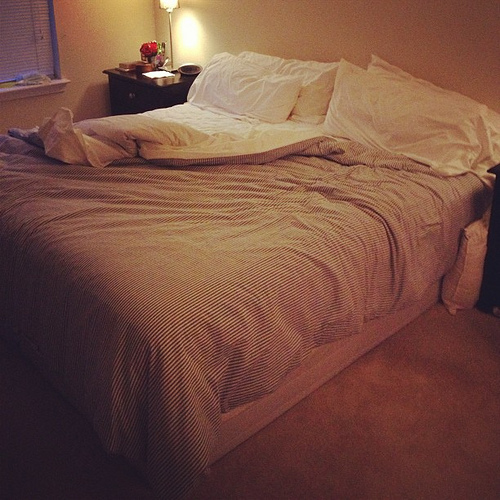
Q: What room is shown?
A: It is a bedroom.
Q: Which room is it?
A: It is a bedroom.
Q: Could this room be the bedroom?
A: Yes, it is the bedroom.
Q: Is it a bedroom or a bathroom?
A: It is a bedroom.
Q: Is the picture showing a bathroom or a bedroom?
A: It is showing a bedroom.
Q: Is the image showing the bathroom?
A: No, the picture is showing the bedroom.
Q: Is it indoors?
A: Yes, it is indoors.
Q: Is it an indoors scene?
A: Yes, it is indoors.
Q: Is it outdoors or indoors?
A: It is indoors.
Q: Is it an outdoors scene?
A: No, it is indoors.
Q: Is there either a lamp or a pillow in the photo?
A: Yes, there is a pillow.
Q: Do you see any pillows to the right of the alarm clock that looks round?
A: Yes, there is a pillow to the right of the alarm clock.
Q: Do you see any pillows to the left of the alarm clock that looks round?
A: No, the pillow is to the right of the alarm clock.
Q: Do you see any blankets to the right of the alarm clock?
A: No, there is a pillow to the right of the alarm clock.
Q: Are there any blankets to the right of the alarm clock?
A: No, there is a pillow to the right of the alarm clock.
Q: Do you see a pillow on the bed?
A: Yes, there is a pillow on the bed.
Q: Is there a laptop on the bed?
A: No, there is a pillow on the bed.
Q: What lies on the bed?
A: The pillow lies on the bed.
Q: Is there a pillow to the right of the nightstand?
A: Yes, there is a pillow to the right of the nightstand.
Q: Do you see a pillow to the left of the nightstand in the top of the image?
A: No, the pillow is to the right of the nightstand.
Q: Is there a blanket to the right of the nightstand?
A: No, there is a pillow to the right of the nightstand.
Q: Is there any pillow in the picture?
A: Yes, there is a pillow.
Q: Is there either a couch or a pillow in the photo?
A: Yes, there is a pillow.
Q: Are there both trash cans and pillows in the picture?
A: No, there is a pillow but no trash cans.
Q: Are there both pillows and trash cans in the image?
A: No, there is a pillow but no trash cans.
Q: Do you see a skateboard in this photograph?
A: No, there are no skateboards.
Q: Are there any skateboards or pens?
A: No, there are no skateboards or pens.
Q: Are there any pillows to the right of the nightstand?
A: Yes, there is a pillow to the right of the nightstand.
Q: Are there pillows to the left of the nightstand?
A: No, the pillow is to the right of the nightstand.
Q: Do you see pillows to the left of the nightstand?
A: No, the pillow is to the right of the nightstand.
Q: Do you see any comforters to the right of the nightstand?
A: No, there is a pillow to the right of the nightstand.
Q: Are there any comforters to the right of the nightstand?
A: No, there is a pillow to the right of the nightstand.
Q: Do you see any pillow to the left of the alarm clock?
A: No, the pillow is to the right of the alarm clock.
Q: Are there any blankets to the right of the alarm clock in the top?
A: No, there is a pillow to the right of the alarm clock.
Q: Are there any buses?
A: No, there are no buses.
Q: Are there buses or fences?
A: No, there are no buses or fences.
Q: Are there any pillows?
A: Yes, there is a pillow.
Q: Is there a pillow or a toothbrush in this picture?
A: Yes, there is a pillow.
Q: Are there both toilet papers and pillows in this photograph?
A: No, there is a pillow but no toilet papers.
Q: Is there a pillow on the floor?
A: Yes, there is a pillow on the floor.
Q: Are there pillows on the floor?
A: Yes, there is a pillow on the floor.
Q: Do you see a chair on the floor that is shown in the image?
A: No, there is a pillow on the floor.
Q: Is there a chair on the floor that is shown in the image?
A: No, there is a pillow on the floor.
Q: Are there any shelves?
A: No, there are no shelves.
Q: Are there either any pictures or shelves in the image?
A: No, there are no shelves or pictures.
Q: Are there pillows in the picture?
A: Yes, there are pillows.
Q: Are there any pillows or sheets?
A: Yes, there are pillows.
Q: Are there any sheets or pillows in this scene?
A: Yes, there are pillows.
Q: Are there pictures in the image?
A: No, there are no pictures.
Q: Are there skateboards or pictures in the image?
A: No, there are no pictures or skateboards.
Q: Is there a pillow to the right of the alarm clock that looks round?
A: Yes, there are pillows to the right of the alarm clock.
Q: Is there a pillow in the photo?
A: Yes, there is a pillow.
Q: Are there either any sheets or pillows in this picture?
A: Yes, there is a pillow.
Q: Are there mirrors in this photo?
A: No, there are no mirrors.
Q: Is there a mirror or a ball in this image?
A: No, there are no mirrors or balls.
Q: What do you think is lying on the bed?
A: The pillow is lying on the bed.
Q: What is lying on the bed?
A: The pillow is lying on the bed.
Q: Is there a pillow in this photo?
A: Yes, there are pillows.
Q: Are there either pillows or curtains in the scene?
A: Yes, there are pillows.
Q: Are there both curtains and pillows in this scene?
A: No, there are pillows but no curtains.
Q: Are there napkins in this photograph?
A: No, there are no napkins.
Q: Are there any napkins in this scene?
A: No, there are no napkins.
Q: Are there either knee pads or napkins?
A: No, there are no napkins or knee pads.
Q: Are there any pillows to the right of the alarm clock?
A: Yes, there are pillows to the right of the alarm clock.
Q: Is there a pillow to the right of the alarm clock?
A: Yes, there are pillows to the right of the alarm clock.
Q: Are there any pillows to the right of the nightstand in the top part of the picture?
A: Yes, there are pillows to the right of the nightstand.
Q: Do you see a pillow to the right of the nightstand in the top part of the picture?
A: Yes, there are pillows to the right of the nightstand.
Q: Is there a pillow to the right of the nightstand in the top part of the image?
A: Yes, there are pillows to the right of the nightstand.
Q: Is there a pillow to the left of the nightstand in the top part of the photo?
A: No, the pillows are to the right of the nightstand.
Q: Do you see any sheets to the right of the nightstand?
A: No, there are pillows to the right of the nightstand.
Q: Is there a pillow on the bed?
A: Yes, there are pillows on the bed.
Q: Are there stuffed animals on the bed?
A: No, there are pillows on the bed.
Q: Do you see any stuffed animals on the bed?
A: No, there are pillows on the bed.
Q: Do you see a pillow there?
A: Yes, there is a pillow.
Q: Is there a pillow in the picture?
A: Yes, there is a pillow.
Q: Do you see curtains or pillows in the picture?
A: Yes, there is a pillow.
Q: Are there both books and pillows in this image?
A: No, there is a pillow but no books.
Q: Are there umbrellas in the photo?
A: No, there are no umbrellas.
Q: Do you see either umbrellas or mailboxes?
A: No, there are no umbrellas or mailboxes.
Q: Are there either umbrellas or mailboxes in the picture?
A: No, there are no umbrellas or mailboxes.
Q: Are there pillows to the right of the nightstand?
A: Yes, there is a pillow to the right of the nightstand.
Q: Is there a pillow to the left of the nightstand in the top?
A: No, the pillow is to the right of the nightstand.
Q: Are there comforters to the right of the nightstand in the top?
A: No, there is a pillow to the right of the nightstand.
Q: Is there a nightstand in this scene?
A: Yes, there is a nightstand.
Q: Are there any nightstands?
A: Yes, there is a nightstand.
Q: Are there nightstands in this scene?
A: Yes, there is a nightstand.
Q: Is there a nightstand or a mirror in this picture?
A: Yes, there is a nightstand.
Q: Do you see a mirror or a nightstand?
A: Yes, there is a nightstand.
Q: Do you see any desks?
A: No, there are no desks.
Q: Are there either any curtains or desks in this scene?
A: No, there are no desks or curtains.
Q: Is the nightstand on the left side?
A: Yes, the nightstand is on the left of the image.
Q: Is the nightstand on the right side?
A: No, the nightstand is on the left of the image.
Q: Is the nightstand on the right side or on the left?
A: The nightstand is on the left of the image.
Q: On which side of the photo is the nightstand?
A: The nightstand is on the left of the image.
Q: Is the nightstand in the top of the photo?
A: Yes, the nightstand is in the top of the image.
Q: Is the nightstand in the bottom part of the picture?
A: No, the nightstand is in the top of the image.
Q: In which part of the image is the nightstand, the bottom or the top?
A: The nightstand is in the top of the image.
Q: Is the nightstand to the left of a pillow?
A: Yes, the nightstand is to the left of a pillow.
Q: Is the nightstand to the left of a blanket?
A: No, the nightstand is to the left of a pillow.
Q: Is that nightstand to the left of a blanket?
A: No, the nightstand is to the left of a pillow.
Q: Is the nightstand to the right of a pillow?
A: No, the nightstand is to the left of a pillow.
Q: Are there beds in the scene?
A: Yes, there is a bed.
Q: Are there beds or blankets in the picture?
A: Yes, there is a bed.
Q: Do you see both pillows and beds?
A: Yes, there are both a bed and a pillow.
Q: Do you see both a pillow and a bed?
A: Yes, there are both a bed and a pillow.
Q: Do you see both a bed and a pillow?
A: Yes, there are both a bed and a pillow.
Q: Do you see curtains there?
A: No, there are no curtains.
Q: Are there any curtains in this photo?
A: No, there are no curtains.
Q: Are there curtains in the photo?
A: No, there are no curtains.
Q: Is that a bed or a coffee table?
A: That is a bed.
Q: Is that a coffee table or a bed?
A: That is a bed.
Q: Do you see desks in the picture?
A: No, there are no desks.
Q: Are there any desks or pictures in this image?
A: No, there are no desks or pictures.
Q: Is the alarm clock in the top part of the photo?
A: Yes, the alarm clock is in the top of the image.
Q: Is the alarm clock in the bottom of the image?
A: No, the alarm clock is in the top of the image.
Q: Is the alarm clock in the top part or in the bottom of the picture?
A: The alarm clock is in the top of the image.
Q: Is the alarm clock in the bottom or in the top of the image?
A: The alarm clock is in the top of the image.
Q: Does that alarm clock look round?
A: Yes, the alarm clock is round.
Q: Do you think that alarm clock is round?
A: Yes, the alarm clock is round.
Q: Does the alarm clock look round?
A: Yes, the alarm clock is round.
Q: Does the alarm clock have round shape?
A: Yes, the alarm clock is round.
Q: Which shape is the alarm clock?
A: The alarm clock is round.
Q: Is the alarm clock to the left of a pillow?
A: Yes, the alarm clock is to the left of a pillow.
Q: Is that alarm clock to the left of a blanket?
A: No, the alarm clock is to the left of a pillow.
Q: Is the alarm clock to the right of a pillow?
A: No, the alarm clock is to the left of a pillow.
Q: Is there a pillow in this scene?
A: Yes, there are pillows.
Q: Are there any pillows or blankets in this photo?
A: Yes, there are pillows.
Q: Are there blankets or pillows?
A: Yes, there are pillows.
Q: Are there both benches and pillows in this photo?
A: No, there are pillows but no benches.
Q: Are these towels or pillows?
A: These are pillows.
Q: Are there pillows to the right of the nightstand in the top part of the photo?
A: Yes, there are pillows to the right of the nightstand.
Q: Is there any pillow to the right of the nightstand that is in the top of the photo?
A: Yes, there are pillows to the right of the nightstand.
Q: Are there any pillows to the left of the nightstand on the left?
A: No, the pillows are to the right of the nightstand.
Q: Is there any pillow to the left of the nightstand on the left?
A: No, the pillows are to the right of the nightstand.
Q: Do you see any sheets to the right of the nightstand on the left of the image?
A: No, there are pillows to the right of the nightstand.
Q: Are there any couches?
A: No, there are no couches.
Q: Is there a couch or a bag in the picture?
A: No, there are no couches or bags.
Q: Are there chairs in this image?
A: No, there are no chairs.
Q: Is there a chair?
A: No, there are no chairs.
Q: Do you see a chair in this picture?
A: No, there are no chairs.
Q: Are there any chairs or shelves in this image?
A: No, there are no chairs or shelves.